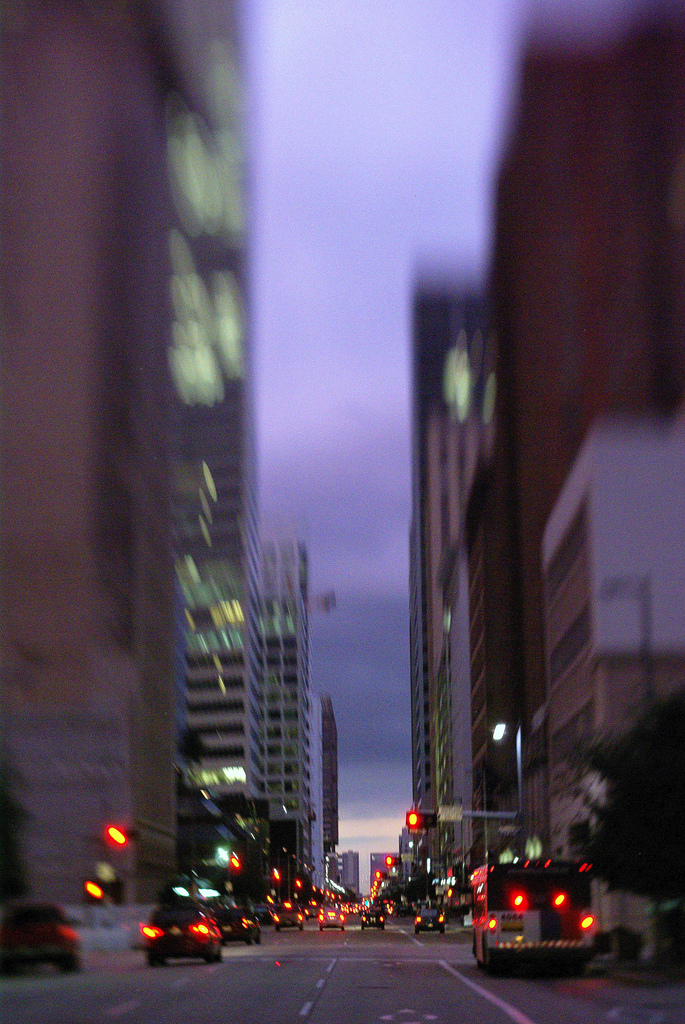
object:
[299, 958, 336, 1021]
lines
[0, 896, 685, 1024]
road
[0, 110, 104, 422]
wall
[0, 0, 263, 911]
building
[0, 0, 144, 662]
wall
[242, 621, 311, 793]
wall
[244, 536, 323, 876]
building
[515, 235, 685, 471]
wall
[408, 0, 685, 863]
building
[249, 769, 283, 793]
window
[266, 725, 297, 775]
window